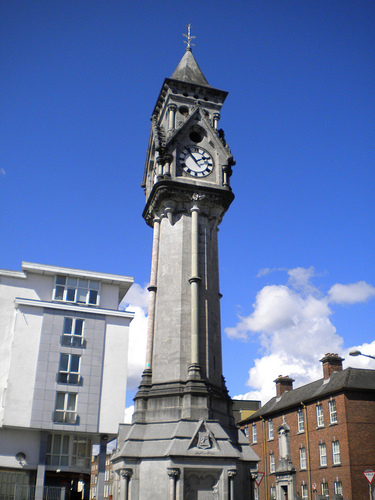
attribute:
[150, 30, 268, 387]
clock tower — outdoors, gray, stone, simple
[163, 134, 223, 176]
clock — white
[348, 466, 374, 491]
sign — yield, triangular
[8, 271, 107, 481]
building — modern, brick, 3 stories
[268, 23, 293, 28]
sky — blue, cloudy, rich blue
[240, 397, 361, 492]
building — brick, old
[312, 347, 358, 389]
chimney — brick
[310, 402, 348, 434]
windows — white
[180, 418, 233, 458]
triangle — gray, stone, carved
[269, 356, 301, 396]
chimney — doubled, brick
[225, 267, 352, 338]
clouds — white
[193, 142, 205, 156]
numbers — roman